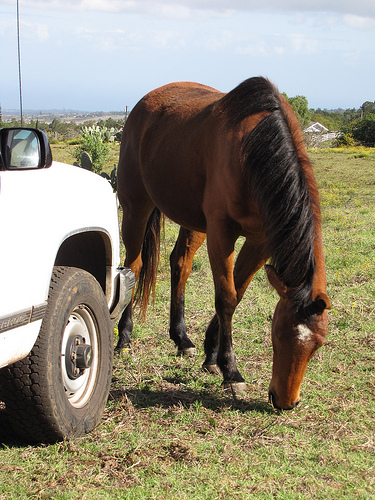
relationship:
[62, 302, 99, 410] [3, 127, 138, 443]
rim from truck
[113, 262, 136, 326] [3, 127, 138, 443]
bumper on truck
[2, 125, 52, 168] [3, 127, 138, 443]
mirror on truck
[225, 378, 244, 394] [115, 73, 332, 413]
hooves of horse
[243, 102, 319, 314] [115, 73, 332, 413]
mane on horse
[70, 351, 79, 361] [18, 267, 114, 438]
nut on tire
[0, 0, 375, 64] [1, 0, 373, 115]
cloud in sky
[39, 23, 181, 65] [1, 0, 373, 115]
cloud in sky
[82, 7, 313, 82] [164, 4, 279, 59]
sky has clouds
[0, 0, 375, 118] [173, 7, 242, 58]
sky has clouds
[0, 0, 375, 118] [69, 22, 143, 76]
sky has clouds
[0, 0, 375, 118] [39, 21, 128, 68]
sky has clouds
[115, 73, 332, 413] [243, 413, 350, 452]
horse eats grass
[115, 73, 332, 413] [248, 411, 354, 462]
horse eats grass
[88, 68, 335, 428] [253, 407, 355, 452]
horse eats grass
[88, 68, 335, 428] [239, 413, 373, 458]
horse eats grass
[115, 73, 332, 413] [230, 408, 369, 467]
horse eats grass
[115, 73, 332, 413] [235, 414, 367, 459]
horse eats grass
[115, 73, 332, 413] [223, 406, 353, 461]
horse eats grass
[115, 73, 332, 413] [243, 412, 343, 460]
horse eats grass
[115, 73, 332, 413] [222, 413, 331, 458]
horse eats grass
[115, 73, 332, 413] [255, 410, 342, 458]
horse eats grass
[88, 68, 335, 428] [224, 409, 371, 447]
horse eats grass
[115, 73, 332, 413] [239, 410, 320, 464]
horse eats grass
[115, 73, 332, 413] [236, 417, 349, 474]
horse eats grass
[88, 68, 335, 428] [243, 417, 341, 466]
horse eats grass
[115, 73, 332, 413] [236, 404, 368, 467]
horse eats grass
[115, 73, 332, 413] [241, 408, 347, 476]
horse eats grass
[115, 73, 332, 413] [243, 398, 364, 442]
horse eats grass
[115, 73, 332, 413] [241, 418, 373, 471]
horse eats grass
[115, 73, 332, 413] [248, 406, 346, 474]
horse eats grass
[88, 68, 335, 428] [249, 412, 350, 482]
horse eats grass